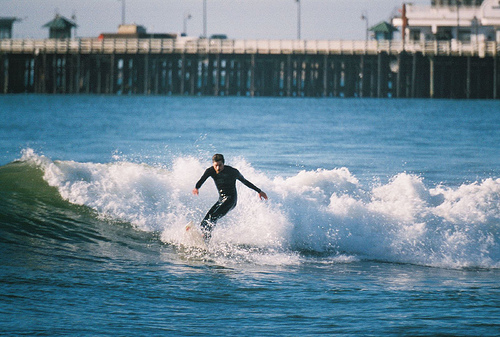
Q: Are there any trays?
A: No, there are no trays.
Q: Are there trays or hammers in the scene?
A: No, there are no trays or hammers.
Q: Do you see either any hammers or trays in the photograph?
A: No, there are no trays or hammers.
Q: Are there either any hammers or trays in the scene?
A: No, there are no trays or hammers.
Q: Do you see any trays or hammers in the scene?
A: No, there are no trays or hammers.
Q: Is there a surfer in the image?
A: Yes, there is a surfer.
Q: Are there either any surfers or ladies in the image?
A: Yes, there is a surfer.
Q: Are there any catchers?
A: No, there are no catchers.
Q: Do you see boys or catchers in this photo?
A: No, there are no catchers or boys.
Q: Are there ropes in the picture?
A: No, there are no ropes.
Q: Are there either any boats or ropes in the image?
A: No, there are no ropes or boats.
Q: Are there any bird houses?
A: No, there are no bird houses.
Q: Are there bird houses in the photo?
A: No, there are no bird houses.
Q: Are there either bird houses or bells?
A: No, there are no bird houses or bells.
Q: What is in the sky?
A: The clouds are in the sky.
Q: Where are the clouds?
A: The clouds are in the sky.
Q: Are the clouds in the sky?
A: Yes, the clouds are in the sky.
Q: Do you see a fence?
A: Yes, there is a fence.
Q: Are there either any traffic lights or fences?
A: Yes, there is a fence.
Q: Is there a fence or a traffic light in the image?
A: Yes, there is a fence.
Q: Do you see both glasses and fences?
A: No, there is a fence but no glasses.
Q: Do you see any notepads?
A: No, there are no notepads.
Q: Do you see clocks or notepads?
A: No, there are no notepads or clocks.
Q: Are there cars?
A: No, there are no cars.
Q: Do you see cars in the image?
A: No, there are no cars.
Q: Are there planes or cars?
A: No, there are no cars or planes.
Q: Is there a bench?
A: No, there are no benches.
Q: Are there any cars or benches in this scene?
A: No, there are no benches or cars.